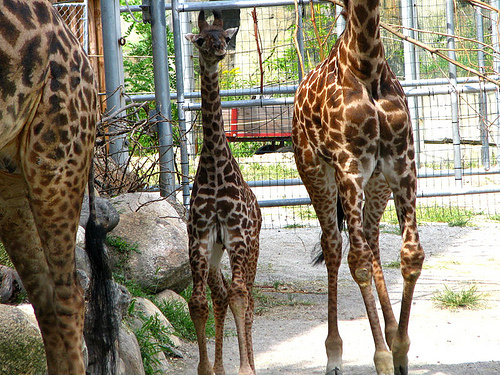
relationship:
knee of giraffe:
[227, 284, 250, 307] [185, 8, 263, 374]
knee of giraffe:
[189, 295, 209, 319] [185, 8, 263, 374]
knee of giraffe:
[211, 288, 231, 310] [185, 8, 263, 374]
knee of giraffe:
[401, 245, 424, 283] [291, 1, 425, 374]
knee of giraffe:
[348, 250, 376, 282] [291, 1, 425, 374]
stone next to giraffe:
[102, 192, 193, 293] [185, 8, 263, 374]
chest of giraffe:
[188, 161, 254, 243] [185, 8, 263, 374]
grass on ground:
[430, 284, 487, 310] [173, 220, 500, 374]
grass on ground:
[387, 256, 403, 270] [173, 220, 500, 374]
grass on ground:
[255, 292, 313, 316] [173, 220, 500, 374]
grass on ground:
[259, 280, 289, 293] [173, 220, 500, 374]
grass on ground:
[445, 217, 469, 228] [173, 220, 500, 374]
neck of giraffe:
[337, 2, 390, 78] [291, 1, 425, 374]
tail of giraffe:
[83, 158, 128, 373] [0, 0, 121, 374]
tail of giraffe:
[310, 235, 327, 271] [291, 1, 425, 374]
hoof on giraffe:
[325, 362, 345, 373] [291, 1, 425, 374]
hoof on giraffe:
[394, 364, 409, 374] [291, 1, 425, 374]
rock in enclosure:
[128, 296, 185, 359] [0, 2, 500, 374]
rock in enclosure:
[156, 289, 190, 319] [0, 2, 500, 374]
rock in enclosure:
[120, 325, 145, 373] [0, 2, 500, 374]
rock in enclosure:
[1, 303, 48, 373] [0, 2, 500, 374]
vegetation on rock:
[148, 297, 196, 343] [156, 289, 190, 319]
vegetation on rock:
[140, 317, 178, 374] [128, 296, 185, 359]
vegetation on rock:
[107, 233, 146, 295] [102, 192, 193, 293]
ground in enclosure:
[173, 220, 500, 374] [0, 2, 500, 374]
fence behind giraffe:
[53, 2, 499, 229] [185, 8, 263, 374]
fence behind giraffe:
[53, 2, 499, 229] [291, 1, 425, 374]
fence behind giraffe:
[53, 2, 499, 229] [0, 0, 121, 374]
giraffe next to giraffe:
[185, 8, 263, 374] [291, 1, 425, 374]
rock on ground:
[128, 296, 185, 359] [173, 220, 500, 374]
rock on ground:
[120, 325, 145, 373] [173, 220, 500, 374]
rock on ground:
[156, 289, 190, 319] [173, 220, 500, 374]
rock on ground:
[1, 303, 48, 373] [173, 220, 500, 374]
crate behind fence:
[219, 104, 298, 139] [53, 2, 499, 229]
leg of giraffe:
[25, 94, 91, 370] [0, 0, 121, 374]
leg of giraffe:
[0, 180, 63, 373] [0, 0, 121, 374]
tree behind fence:
[120, 2, 180, 156] [53, 2, 499, 229]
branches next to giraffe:
[92, 81, 202, 225] [185, 8, 263, 374]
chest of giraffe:
[336, 87, 412, 172] [291, 1, 425, 374]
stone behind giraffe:
[102, 192, 193, 293] [0, 0, 121, 374]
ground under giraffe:
[173, 220, 500, 374] [185, 8, 263, 374]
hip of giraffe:
[27, 3, 98, 162] [0, 0, 121, 374]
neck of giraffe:
[199, 63, 228, 149] [185, 8, 263, 374]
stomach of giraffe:
[1, 120, 27, 152] [0, 0, 121, 374]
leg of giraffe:
[225, 234, 253, 374] [185, 8, 263, 374]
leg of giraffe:
[189, 233, 209, 373] [185, 8, 263, 374]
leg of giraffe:
[207, 269, 230, 374] [185, 8, 263, 374]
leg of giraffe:
[307, 183, 346, 373] [291, 1, 425, 374]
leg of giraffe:
[336, 181, 396, 374] [291, 1, 425, 374]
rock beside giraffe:
[156, 289, 190, 319] [185, 8, 263, 374]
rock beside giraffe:
[128, 296, 185, 359] [185, 8, 263, 374]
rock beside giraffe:
[120, 325, 145, 373] [185, 8, 263, 374]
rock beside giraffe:
[1, 303, 48, 373] [0, 0, 121, 374]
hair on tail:
[86, 217, 122, 374] [83, 158, 128, 373]